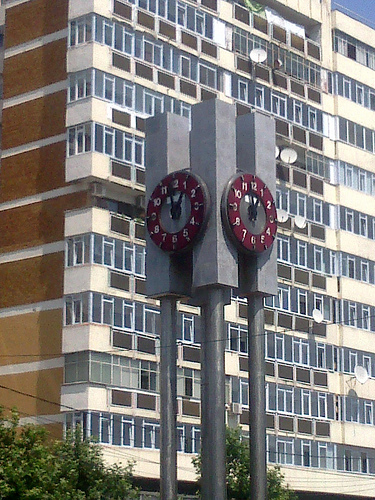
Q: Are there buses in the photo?
A: No, there are no buses.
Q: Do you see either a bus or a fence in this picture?
A: No, there are no buses or fences.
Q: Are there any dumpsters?
A: No, there are no dumpsters.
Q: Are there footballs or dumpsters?
A: No, there are no dumpsters or footballs.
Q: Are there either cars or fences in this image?
A: No, there are no cars or fences.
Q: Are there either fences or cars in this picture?
A: No, there are no cars or fences.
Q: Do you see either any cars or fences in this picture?
A: No, there are no cars or fences.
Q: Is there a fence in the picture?
A: No, there are no fences.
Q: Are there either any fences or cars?
A: No, there are no fences or cars.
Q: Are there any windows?
A: Yes, there are windows.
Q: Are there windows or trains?
A: Yes, there are windows.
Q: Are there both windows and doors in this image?
A: No, there are windows but no doors.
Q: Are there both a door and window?
A: No, there are windows but no doors.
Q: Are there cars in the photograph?
A: No, there are no cars.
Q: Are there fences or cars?
A: No, there are no cars or fences.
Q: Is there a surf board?
A: No, there are no surfboards.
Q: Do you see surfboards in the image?
A: No, there are no surfboards.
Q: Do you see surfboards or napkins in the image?
A: No, there are no surfboards or napkins.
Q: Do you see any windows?
A: Yes, there are windows.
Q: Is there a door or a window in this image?
A: Yes, there are windows.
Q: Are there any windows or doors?
A: Yes, there are windows.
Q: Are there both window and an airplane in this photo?
A: No, there are windows but no airplanes.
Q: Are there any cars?
A: No, there are no cars.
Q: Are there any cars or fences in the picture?
A: No, there are no cars or fences.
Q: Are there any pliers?
A: No, there are no pliers.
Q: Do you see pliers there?
A: No, there are no pliers.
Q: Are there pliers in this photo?
A: No, there are no pliers.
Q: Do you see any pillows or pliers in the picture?
A: No, there are no pliers or pillows.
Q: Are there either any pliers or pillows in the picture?
A: No, there are no pliers or pillows.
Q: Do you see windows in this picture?
A: Yes, there is a window.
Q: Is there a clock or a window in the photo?
A: Yes, there is a window.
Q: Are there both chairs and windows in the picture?
A: No, there is a window but no chairs.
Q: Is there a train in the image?
A: No, there are no trains.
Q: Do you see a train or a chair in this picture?
A: No, there are no trains or chairs.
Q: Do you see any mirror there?
A: No, there are no mirrors.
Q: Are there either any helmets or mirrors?
A: No, there are no mirrors or helmets.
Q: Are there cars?
A: No, there are no cars.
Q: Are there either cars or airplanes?
A: No, there are no cars or airplanes.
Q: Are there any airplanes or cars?
A: No, there are no cars or airplanes.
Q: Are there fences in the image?
A: No, there are no fences.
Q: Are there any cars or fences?
A: No, there are no fences or cars.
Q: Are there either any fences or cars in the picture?
A: No, there are no fences or cars.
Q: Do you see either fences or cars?
A: No, there are no fences or cars.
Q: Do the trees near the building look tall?
A: Yes, the trees are tall.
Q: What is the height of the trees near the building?
A: The trees are tall.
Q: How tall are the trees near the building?
A: The trees are tall.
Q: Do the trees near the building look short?
A: No, the trees are tall.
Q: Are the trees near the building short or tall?
A: The trees are tall.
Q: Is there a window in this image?
A: Yes, there is a window.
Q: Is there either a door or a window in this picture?
A: Yes, there is a window.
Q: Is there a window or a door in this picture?
A: Yes, there is a window.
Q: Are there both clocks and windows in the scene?
A: Yes, there are both a window and a clock.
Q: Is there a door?
A: No, there are no doors.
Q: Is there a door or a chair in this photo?
A: No, there are no doors or chairs.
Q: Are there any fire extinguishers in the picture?
A: No, there are no fire extinguishers.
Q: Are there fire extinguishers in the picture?
A: No, there are no fire extinguishers.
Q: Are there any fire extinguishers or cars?
A: No, there are no fire extinguishers or cars.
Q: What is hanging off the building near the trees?
A: The powerlines are hanging off the building.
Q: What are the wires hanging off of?
A: The wires are hanging off the building.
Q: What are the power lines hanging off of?
A: The wires are hanging off the building.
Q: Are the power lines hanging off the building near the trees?
A: Yes, the power lines are hanging off the building.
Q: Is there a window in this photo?
A: Yes, there is a window.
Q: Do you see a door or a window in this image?
A: Yes, there is a window.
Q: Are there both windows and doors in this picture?
A: No, there is a window but no doors.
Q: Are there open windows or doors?
A: Yes, there is an open window.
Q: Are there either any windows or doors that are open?
A: Yes, the window is open.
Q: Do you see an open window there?
A: Yes, there is an open window.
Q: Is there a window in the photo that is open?
A: Yes, there is a window that is open.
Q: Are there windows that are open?
A: Yes, there is a window that is open.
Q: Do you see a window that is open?
A: Yes, there is a window that is open.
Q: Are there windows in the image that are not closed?
A: Yes, there is a open window.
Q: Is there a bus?
A: No, there are no buses.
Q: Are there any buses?
A: No, there are no buses.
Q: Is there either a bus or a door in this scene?
A: No, there are no buses or doors.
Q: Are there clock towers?
A: Yes, there is a clock tower.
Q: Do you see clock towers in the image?
A: Yes, there is a clock tower.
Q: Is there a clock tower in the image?
A: Yes, there is a clock tower.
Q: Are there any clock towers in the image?
A: Yes, there is a clock tower.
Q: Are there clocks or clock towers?
A: Yes, there is a clock tower.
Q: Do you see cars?
A: No, there are no cars.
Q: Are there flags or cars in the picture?
A: No, there are no cars or flags.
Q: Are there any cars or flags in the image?
A: No, there are no cars or flags.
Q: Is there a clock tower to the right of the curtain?
A: Yes, there is a clock tower to the right of the curtain.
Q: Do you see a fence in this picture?
A: No, there are no fences.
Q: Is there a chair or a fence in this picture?
A: No, there are no fences or chairs.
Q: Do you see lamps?
A: No, there are no lamps.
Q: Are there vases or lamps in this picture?
A: No, there are no lamps or vases.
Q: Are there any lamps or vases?
A: No, there are no lamps or vases.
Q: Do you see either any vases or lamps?
A: No, there are no lamps or vases.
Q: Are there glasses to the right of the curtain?
A: No, there are clocks to the right of the curtain.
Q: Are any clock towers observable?
A: Yes, there is a clock tower.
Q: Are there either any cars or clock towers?
A: Yes, there is a clock tower.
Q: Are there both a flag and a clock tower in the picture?
A: No, there is a clock tower but no flags.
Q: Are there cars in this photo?
A: No, there are no cars.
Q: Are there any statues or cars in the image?
A: No, there are no cars or statues.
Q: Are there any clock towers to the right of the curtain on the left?
A: Yes, there is a clock tower to the right of the curtain.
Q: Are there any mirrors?
A: No, there are no mirrors.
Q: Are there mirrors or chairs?
A: No, there are no mirrors or chairs.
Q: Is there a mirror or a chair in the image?
A: No, there are no mirrors or chairs.